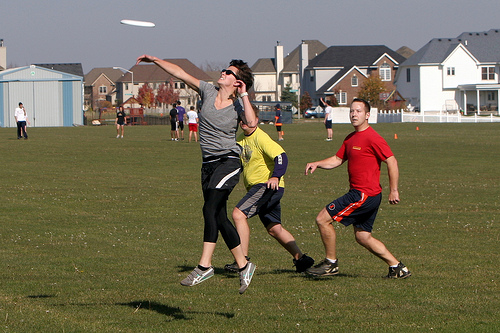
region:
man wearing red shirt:
[307, 84, 410, 288]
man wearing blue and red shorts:
[317, 82, 415, 294]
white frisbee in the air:
[115, 13, 172, 45]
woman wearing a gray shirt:
[133, 30, 260, 295]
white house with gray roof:
[401, 25, 486, 117]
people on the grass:
[148, 36, 426, 199]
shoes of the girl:
[177, 250, 265, 308]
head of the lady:
[201, 50, 266, 110]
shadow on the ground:
[110, 281, 174, 330]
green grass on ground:
[46, 210, 145, 272]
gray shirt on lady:
[166, 78, 254, 168]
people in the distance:
[1, 82, 199, 163]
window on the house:
[364, 58, 402, 90]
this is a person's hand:
[232, 75, 261, 131]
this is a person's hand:
[369, 130, 406, 207]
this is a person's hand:
[301, 120, 351, 174]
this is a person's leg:
[350, 183, 412, 280]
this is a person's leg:
[230, 175, 276, 277]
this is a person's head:
[343, 91, 380, 135]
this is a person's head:
[212, 52, 261, 99]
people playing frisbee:
[103, 11, 438, 301]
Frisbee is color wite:
[115, 8, 161, 37]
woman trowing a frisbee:
[110, 8, 270, 306]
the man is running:
[303, 83, 430, 295]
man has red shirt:
[298, 95, 430, 290]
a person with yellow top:
[218, 93, 315, 290]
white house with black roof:
[397, 31, 497, 120]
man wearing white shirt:
[8, 95, 38, 142]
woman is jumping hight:
[99, 9, 276, 302]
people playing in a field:
[7, 39, 493, 331]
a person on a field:
[179, 30, 286, 305]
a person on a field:
[329, 90, 366, 244]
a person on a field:
[246, 115, 279, 243]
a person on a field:
[315, 91, 328, 146]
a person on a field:
[272, 100, 284, 175]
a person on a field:
[104, 95, 136, 152]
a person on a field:
[16, 92, 37, 161]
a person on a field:
[159, 104, 174, 145]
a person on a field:
[173, 102, 183, 139]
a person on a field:
[189, 108, 198, 161]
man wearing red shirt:
[294, 88, 423, 303]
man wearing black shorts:
[296, 163, 392, 271]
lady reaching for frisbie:
[105, 24, 261, 331]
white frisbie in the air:
[108, 11, 185, 51]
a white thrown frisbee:
[118, 16, 156, 26]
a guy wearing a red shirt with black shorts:
[304, 98, 409, 281]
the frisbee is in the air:
[120, 18, 155, 30]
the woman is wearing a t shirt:
[195, 79, 253, 169]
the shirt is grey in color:
[192, 77, 253, 166]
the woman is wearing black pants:
[200, 155, 250, 252]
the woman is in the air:
[137, 51, 262, 295]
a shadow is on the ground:
[79, 290, 236, 325]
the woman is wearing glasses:
[221, 65, 246, 85]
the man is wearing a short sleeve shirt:
[337, 127, 394, 201]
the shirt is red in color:
[331, 127, 392, 201]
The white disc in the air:
[106, 7, 156, 44]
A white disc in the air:
[111, 8, 157, 39]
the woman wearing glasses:
[131, 37, 272, 299]